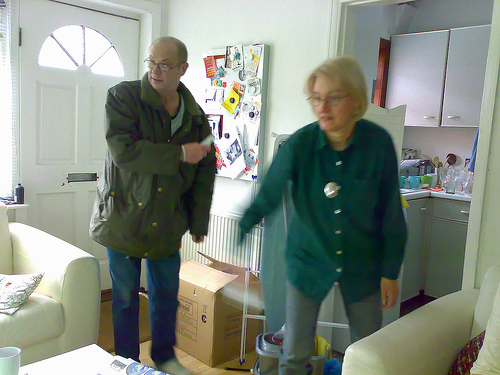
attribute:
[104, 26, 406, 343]
couple — old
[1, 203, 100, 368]
couch — white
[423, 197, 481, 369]
cabinets — white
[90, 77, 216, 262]
jacket — green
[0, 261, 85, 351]
pillow — small , red 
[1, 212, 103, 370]
sofa — White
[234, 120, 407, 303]
shirt — blue 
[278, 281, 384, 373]
pants — grey 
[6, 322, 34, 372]
cup — paper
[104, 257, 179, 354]
jeans — blue 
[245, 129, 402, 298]
shirt — green 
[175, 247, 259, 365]
box — brown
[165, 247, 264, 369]
box — Cardboard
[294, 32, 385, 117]
hair — short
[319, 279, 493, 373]
couch — white